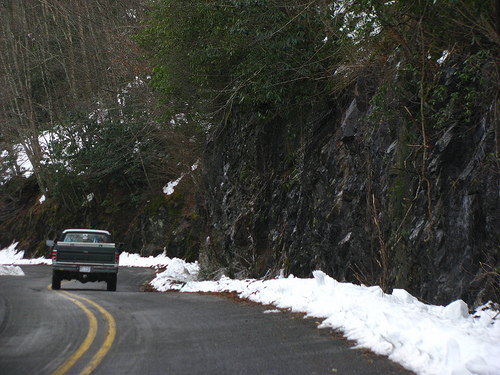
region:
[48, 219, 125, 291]
A truck on the road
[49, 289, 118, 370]
Double yellow lines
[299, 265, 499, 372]
Snow along the side of the road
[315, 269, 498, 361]
White clumps of snow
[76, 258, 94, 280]
A license plate on the truck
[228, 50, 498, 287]
Mountains on the side of the road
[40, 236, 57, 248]
A side view mirror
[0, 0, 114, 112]
trees with no leaves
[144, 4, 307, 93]
Green leaves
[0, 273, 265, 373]
A black road with lines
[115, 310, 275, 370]
Road is grey color.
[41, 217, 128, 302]
One car is on road.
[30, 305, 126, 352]
Yellow lines on road.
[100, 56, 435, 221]
Trees are in sides of the road.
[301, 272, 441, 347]
Snow is white color.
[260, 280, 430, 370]
Snow is on both sides of the road.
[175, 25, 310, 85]
Leaves are green color.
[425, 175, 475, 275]
Rocks are black color.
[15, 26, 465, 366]
Day time picture.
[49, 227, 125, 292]
Car is black and grey color.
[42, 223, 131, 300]
Car running in right road.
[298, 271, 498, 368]
Snow on right side of road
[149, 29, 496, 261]
Rocky mountain on right side of road.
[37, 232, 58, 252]
Left mirror of truck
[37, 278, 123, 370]
Yellow lines on center of road.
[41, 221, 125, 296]
Truck has space to load on back.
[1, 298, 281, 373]
Road does not have snow.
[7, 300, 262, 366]
Road is paved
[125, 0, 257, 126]
Bush on rock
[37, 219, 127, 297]
Truck on road is tan.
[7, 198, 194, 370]
pickup truck going downhill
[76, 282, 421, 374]
road recently cleared of snow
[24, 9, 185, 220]
forest during winter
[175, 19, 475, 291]
forest on a cliff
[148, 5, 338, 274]
trees hanging over cliff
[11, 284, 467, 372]
wet road after recently snowing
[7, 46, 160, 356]
truck taking a turn downhill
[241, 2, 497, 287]
vines and trees hanging over rocks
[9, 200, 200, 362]
pickup truck without braking lights on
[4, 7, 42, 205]
trees without leaves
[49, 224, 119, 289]
Truck driving on the road.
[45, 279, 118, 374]
Two yellow lines on the road.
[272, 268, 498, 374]
White snow at the side of the road.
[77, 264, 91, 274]
White license plate on a truck.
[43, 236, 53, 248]
Drivers rear view mirror.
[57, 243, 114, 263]
Truck bed gate on the back of the truck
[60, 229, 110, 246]
Back windshield of a truck.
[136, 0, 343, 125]
Large green tree growing off a hillside.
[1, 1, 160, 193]
Several trees on the left top above the truck.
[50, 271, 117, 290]
Back black tires of a truck.